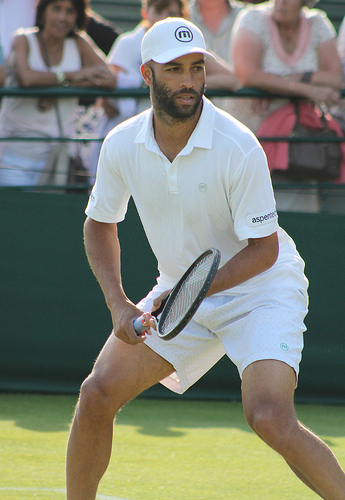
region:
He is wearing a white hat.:
[137, 15, 219, 72]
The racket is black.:
[126, 252, 222, 333]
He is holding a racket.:
[68, 26, 326, 453]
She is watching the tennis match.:
[40, 5, 84, 73]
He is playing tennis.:
[69, 15, 311, 428]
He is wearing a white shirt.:
[79, 107, 311, 287]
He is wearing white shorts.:
[117, 235, 332, 378]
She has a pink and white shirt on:
[236, 1, 330, 110]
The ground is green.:
[125, 400, 252, 497]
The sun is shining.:
[20, 164, 338, 495]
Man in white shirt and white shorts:
[55, 15, 343, 498]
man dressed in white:
[38, 17, 343, 499]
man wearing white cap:
[53, 14, 343, 498]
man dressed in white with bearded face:
[57, 15, 340, 498]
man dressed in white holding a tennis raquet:
[56, 16, 343, 497]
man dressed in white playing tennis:
[46, 12, 343, 496]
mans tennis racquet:
[131, 246, 221, 340]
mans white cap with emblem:
[139, 16, 215, 72]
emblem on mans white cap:
[172, 23, 193, 43]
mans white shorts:
[114, 241, 309, 395]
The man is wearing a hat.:
[130, 9, 227, 128]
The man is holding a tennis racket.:
[89, 235, 227, 345]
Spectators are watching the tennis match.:
[1, 0, 338, 196]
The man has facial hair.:
[138, 51, 219, 120]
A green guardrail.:
[0, 85, 339, 201]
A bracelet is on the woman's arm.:
[40, 60, 71, 90]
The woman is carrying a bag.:
[0, 15, 66, 206]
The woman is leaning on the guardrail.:
[226, 0, 340, 181]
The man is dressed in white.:
[85, 102, 319, 371]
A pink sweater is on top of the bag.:
[249, 95, 341, 195]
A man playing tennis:
[52, 15, 339, 495]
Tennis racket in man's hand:
[84, 220, 232, 356]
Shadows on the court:
[20, 374, 240, 461]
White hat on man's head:
[129, 10, 222, 82]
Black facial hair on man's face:
[135, 70, 213, 122]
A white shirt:
[76, 111, 306, 299]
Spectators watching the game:
[3, 0, 343, 190]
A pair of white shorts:
[121, 260, 321, 397]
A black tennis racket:
[110, 244, 229, 344]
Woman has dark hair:
[26, 0, 97, 54]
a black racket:
[114, 248, 224, 341]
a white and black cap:
[139, 16, 218, 64]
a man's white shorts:
[115, 271, 310, 395]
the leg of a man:
[236, 309, 342, 497]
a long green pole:
[0, 83, 342, 103]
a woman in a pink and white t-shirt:
[231, 3, 333, 125]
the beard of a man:
[147, 63, 207, 118]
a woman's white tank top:
[0, 32, 85, 156]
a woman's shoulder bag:
[33, 29, 92, 190]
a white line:
[0, 477, 63, 495]